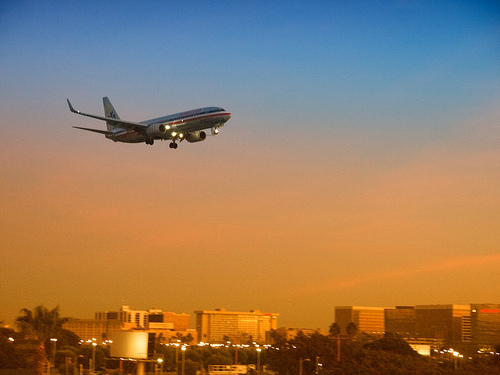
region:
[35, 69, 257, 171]
the plane is in the sky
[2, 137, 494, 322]
this part of the sky is pinkish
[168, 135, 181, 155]
the planes landing gear is coming down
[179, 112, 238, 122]
a red stripe is on the side of the plane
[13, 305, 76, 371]
The top of a Palm Tree is visible in the distance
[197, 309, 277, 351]
a high rise building in the distance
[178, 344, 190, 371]
Street lights are visible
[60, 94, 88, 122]
the tip of the wing is angled up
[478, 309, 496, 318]
red lettering on a building sign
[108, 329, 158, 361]
an empty billbord has a solid white background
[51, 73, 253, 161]
comercial airplane in air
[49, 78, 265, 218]
airliner in flight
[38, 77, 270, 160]
airplane with its lights on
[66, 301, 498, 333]
skyscrapers in the horizon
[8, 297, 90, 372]
tall palm tree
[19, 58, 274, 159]
airliner in flight at dusk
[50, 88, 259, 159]
american airlines plane in flight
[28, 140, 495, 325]
orange glow of dusk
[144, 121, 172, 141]
right side engine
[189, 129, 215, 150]
left side engine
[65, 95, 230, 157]
Airplane flying over a city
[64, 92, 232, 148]
Plane flying in the air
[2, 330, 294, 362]
Lights shining in the street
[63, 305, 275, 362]
Tall buildings in the city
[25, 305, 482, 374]
Trees beside tall buildings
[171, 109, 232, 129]
Red and white marks on plane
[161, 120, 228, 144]
Lights shining on plane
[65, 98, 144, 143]
Right wings of plane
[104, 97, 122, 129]
White tail of plane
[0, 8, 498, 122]
Clear blue colored sky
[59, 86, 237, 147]
airplane in flight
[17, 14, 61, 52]
white clouds in blue sky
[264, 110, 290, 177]
white clouds in blue sky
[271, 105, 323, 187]
white clouds in blue sky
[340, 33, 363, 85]
white clouds in blue sky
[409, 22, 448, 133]
white clouds in blue sky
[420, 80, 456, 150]
white clouds in blue sky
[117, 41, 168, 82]
white clouds in blue sky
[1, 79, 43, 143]
white clouds in blue sky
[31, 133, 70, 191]
white clouds in blue sky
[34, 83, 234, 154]
gray airplane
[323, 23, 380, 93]
white clouds in blue sky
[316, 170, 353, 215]
white clouds in blue sky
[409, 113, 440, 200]
white clouds in blue sky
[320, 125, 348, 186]
white clouds in blue sky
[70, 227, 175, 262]
white clouds in blue sky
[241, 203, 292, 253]
white clouds in blue sky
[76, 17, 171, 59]
white clouds in blue sky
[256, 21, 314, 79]
white clouds in blue sky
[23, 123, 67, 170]
white clouds in blue sky